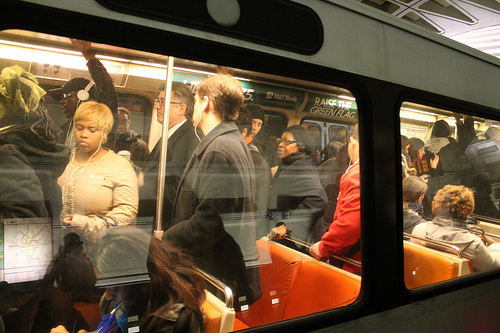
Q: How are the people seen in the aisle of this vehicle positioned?
A: Standing.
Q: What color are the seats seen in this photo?
A: Orange.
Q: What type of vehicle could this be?
A: Commuter train.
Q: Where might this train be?
A: In subway.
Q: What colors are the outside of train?
A: Black and gray.